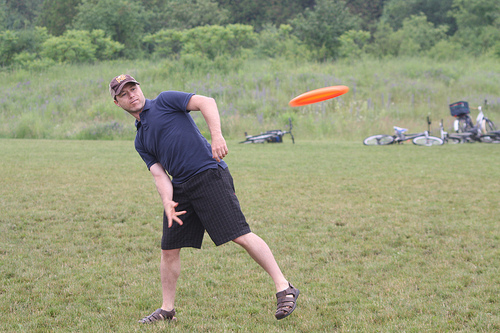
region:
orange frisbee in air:
[286, 71, 351, 112]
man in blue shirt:
[96, 70, 301, 331]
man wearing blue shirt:
[106, 62, 300, 324]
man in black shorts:
[108, 68, 305, 323]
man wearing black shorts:
[110, 75, 295, 325]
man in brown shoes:
[106, 71, 302, 331]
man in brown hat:
[104, 70, 167, 137]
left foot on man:
[266, 281, 313, 329]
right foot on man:
[133, 300, 187, 331]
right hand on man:
[151, 185, 193, 224]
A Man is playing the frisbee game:
[101, 44, 298, 330]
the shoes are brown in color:
[255, 274, 322, 331]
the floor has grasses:
[326, 243, 396, 324]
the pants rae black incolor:
[167, 180, 249, 224]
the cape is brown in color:
[98, 59, 150, 107]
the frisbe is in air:
[273, 53, 365, 146]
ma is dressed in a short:
[133, 113, 245, 317]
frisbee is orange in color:
[298, 83, 350, 163]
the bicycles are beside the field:
[364, 85, 490, 189]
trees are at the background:
[205, 22, 290, 72]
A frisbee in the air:
[281, 75, 352, 115]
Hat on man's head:
[100, 65, 150, 120]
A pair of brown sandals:
[130, 275, 305, 326]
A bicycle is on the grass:
[356, 106, 446, 147]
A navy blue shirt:
[125, 85, 230, 186]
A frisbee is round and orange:
[280, 75, 355, 115]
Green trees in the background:
[0, 0, 497, 72]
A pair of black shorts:
[150, 160, 255, 255]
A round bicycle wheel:
[405, 127, 445, 152]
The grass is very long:
[1, 55, 497, 145]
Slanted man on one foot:
[105, 69, 300, 329]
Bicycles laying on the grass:
[231, 114, 498, 154]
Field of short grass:
[0, 138, 497, 330]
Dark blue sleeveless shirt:
[117, 89, 235, 184]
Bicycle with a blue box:
[445, 98, 492, 142]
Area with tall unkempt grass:
[0, 63, 498, 139]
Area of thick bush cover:
[0, 0, 498, 71]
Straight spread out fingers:
[157, 200, 189, 229]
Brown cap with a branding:
[105, 72, 142, 97]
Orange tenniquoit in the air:
[285, 81, 352, 110]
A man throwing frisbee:
[110, 75, 296, 323]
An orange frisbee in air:
[287, 84, 348, 107]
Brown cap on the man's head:
[110, 73, 138, 98]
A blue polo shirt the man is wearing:
[133, 92, 226, 182]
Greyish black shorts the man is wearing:
[160, 167, 248, 248]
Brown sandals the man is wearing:
[142, 283, 299, 325]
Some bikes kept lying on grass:
[240, 117, 499, 144]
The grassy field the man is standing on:
[0, 136, 497, 327]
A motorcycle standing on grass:
[447, 97, 492, 132]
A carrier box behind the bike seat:
[447, 98, 467, 113]